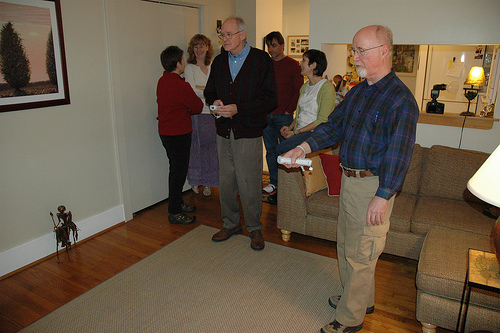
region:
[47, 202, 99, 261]
A small statuette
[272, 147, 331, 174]
Hand holding a video game controller.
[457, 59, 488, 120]
A lamp that's turned on.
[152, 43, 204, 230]
A person talking turned away from viewer.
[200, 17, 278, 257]
A man playing a video game.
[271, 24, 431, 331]
Man in blue shirt playing a video game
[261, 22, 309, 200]
A man standing in the background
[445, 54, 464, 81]
A paper attached by magnet to the fridge.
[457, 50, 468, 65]
Reflection from a refrigerator surface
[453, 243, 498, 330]
Part of a table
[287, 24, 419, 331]
Man wearing a plaid shirt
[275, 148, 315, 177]
Game remote in man's hand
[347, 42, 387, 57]
Glasses on man's face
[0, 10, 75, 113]
Picture hanging on wall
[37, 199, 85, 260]
Figurine on the floor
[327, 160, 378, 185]
Belt around man's waist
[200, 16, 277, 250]
Man wearing a plaid sweater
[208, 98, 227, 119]
Game remote in man's hands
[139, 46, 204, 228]
Woman wearing a red sweater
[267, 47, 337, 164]
Woman sitting on edge of couch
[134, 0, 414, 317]
group of people standing in room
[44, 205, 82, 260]
metal statue in room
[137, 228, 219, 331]
grey carpet in room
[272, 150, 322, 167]
white wii mote inhand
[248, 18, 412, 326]
man playing with wii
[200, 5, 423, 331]
two men playing wii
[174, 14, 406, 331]
two men playing video games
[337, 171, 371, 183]
brown belt on pants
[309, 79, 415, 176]
plaid button down shirt tucked in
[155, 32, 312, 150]
group of people gathered talking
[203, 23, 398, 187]
two men holding game controllers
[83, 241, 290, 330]
a rug on the floor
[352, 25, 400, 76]
a man wearing glasses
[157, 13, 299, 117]
people standing around a door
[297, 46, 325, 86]
a woman with short hair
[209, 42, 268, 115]
a man wearing a blue shirt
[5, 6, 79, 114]
a picture hanging on a wall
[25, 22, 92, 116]
a framed picture on a wall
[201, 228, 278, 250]
a man wearing brown shoes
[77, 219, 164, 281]
a hard wood floor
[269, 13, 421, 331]
man is holding wii remote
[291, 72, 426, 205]
man wearing blue dress shirt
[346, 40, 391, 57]
man on left wearing glasses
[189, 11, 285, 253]
man on right holding wii remote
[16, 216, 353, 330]
gray rug on the floor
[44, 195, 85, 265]
small metal statue on floor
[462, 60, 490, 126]
lamp sitting on counter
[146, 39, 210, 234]
woman wearing red shirt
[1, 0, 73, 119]
painting on left wall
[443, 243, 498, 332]
small table by couch